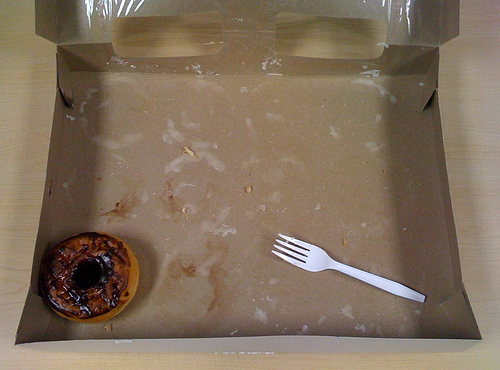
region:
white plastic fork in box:
[268, 228, 435, 312]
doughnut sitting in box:
[28, 219, 174, 336]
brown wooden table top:
[0, 58, 47, 169]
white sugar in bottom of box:
[147, 111, 237, 183]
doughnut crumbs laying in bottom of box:
[156, 133, 215, 165]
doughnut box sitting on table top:
[0, 0, 477, 369]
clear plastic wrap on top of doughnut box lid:
[63, 0, 424, 67]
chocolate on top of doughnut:
[46, 239, 128, 311]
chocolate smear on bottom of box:
[96, 176, 171, 225]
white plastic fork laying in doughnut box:
[228, 201, 464, 343]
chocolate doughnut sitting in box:
[21, 224, 152, 324]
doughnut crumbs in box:
[179, 128, 265, 210]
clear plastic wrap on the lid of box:
[72, 1, 414, 70]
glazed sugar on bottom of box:
[196, 209, 245, 237]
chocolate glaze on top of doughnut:
[97, 249, 124, 274]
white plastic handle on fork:
[329, 251, 435, 321]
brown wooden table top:
[448, 55, 498, 190]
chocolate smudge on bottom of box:
[89, 194, 153, 223]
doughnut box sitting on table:
[18, 47, 495, 359]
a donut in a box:
[37, 225, 144, 325]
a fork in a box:
[268, 230, 440, 315]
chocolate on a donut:
[40, 232, 131, 314]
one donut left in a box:
[30, 70, 443, 325]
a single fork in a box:
[250, 189, 441, 329]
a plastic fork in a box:
[257, 227, 448, 309]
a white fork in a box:
[265, 229, 445, 321]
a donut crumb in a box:
[180, 141, 200, 163]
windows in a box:
[105, 12, 392, 65]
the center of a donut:
[65, 257, 110, 294]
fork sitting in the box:
[260, 212, 430, 301]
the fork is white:
[249, 225, 441, 325]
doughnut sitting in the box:
[37, 230, 136, 320]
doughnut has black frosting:
[50, 231, 140, 315]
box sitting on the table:
[39, 45, 469, 332]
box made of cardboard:
[39, 65, 462, 339]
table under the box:
[5, 105, 62, 261]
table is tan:
[5, 101, 70, 275]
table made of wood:
[8, 60, 78, 275]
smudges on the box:
[70, 77, 338, 304]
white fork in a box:
[268, 208, 429, 329]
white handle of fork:
[328, 248, 432, 323]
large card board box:
[4, 65, 459, 359]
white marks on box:
[154, 121, 216, 172]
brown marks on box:
[105, 192, 146, 224]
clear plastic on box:
[278, 2, 370, 44]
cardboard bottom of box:
[25, 41, 473, 365]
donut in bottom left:
[38, 218, 136, 320]